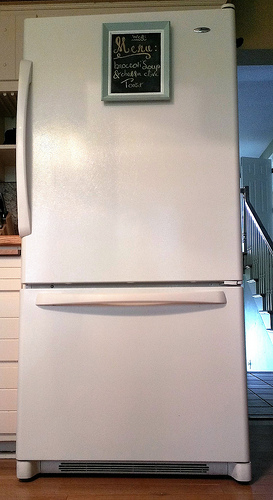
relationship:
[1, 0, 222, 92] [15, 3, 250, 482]
white cupboard near fridge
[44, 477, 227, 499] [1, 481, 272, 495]
floor made of wood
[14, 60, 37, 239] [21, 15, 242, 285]
handle on fridge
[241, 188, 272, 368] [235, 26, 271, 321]
stairs in room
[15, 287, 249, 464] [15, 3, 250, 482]
bottom half of fridge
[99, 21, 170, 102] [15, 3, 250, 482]
menu magnet on fridge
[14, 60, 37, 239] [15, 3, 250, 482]
handle on fridge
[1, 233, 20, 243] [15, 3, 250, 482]
brown counter near fridge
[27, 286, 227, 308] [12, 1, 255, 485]
handle on freezer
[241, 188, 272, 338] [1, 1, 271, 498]
stairs outside of kitchen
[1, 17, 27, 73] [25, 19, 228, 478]
cabinet near fridge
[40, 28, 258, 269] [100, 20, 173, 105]
fridge has board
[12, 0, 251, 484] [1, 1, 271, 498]
fridge in kitchen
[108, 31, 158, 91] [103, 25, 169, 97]
writing on board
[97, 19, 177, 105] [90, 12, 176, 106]
frame on board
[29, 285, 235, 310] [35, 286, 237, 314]
handle on freezer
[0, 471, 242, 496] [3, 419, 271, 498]
wood on floor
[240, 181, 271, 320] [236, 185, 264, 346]
railing on steps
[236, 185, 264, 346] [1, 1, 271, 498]
steps outside kitchen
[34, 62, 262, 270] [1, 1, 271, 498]
door outside kitchen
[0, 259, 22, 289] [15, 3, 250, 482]
drawer near fridge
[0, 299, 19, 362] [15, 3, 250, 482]
drawer near fridge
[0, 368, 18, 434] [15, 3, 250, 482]
drawer near fridge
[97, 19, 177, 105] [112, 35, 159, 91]
frame on sign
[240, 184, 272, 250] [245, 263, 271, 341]
rail near stairs